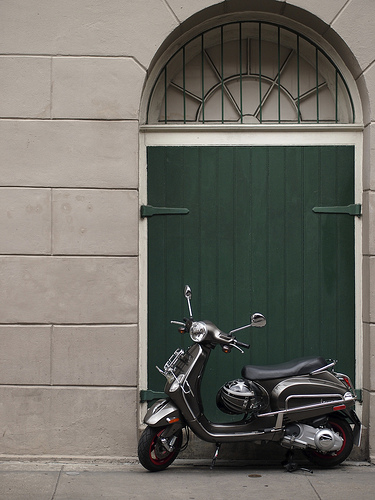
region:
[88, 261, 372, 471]
a bike parked on the sidewalk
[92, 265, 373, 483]
a black bike parked on the sidewalk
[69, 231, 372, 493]
a bike parked in front of a door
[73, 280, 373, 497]
a black bike parked in front of door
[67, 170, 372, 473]
a bike parked in front of green door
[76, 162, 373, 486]
a black bike parked in front of green door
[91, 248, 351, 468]
a bike with a helmet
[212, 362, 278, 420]
a helmet with a star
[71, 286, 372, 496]
a bike with red and black tires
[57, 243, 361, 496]
a motorcycle on sidewalk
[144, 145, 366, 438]
A green wooden door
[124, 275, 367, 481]
A shiny grey scooter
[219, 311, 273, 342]
Chrome plated side view mirror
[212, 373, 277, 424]
Multicolored helmet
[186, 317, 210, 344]
A glass head lamp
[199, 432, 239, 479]
A strong steel kick stand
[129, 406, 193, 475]
Small black tire on a red rim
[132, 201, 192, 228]
Green door hinge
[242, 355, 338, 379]
Soft black scooter seat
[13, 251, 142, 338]
Tan stone work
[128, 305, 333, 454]
motorcycle in front of door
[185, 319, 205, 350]
large headlight on front of cycle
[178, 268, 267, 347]
chrome rear-view mirrors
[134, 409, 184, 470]
small black front wheel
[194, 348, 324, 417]
silver helmet under seat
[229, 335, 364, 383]
grey seat on cycle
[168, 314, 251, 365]
grey and black handlebars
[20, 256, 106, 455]
light grey bricks on wall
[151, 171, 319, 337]
door behind cycle is green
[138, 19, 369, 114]
arched doorway above cycle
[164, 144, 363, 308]
oversized door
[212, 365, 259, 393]
star on the side of helmet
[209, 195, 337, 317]
door is green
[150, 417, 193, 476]
inside the tires are red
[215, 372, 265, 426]
helmet hanging on the scooter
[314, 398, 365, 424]
reflector on side of scooter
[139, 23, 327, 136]
window over the door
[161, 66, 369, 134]
window is in the shape of a half moon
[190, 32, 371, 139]
window has bars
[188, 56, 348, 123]
bars are painted green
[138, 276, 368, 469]
the moped is parked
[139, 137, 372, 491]
the door is closed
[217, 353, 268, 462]
the helmet on the chair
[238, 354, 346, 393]
the chair is black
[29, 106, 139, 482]
the wall is concrete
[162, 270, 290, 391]
the mirror is silver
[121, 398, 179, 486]
the tire is black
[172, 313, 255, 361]
the headlight is off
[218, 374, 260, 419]
the helmet is black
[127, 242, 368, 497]
the moped in front of the door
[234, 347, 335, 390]
A black leather seat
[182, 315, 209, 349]
Round headlight of a motorbike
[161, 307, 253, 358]
The handlebars of a motorbike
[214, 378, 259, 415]
a black and white helmet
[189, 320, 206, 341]
a motorbike front headlight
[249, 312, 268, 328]
a side view mirror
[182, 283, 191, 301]
a side view mirror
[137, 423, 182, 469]
a motor bike front tire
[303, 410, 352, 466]
a motor bike rear tire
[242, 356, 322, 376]
a motor bike black seat